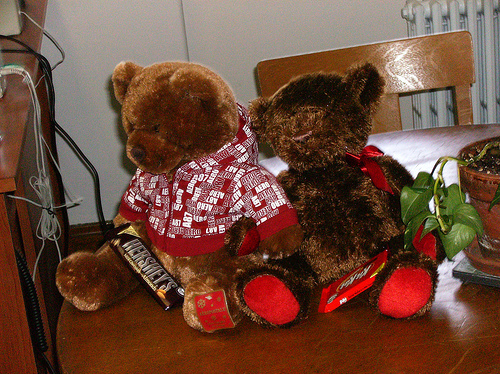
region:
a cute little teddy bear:
[51, 59, 303, 334]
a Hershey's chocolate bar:
[107, 226, 188, 317]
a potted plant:
[398, 133, 497, 288]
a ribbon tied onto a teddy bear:
[341, 141, 396, 200]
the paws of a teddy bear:
[230, 256, 442, 328]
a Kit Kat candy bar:
[314, 248, 394, 317]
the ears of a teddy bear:
[110, 56, 225, 109]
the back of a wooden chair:
[254, 26, 480, 129]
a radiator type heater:
[391, 1, 498, 131]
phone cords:
[2, 57, 85, 288]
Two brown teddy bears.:
[42, 21, 482, 335]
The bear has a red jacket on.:
[49, 67, 278, 339]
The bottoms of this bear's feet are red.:
[240, 262, 450, 335]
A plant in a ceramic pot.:
[400, 108, 497, 287]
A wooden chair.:
[250, 27, 479, 144]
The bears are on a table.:
[39, 9, 489, 372]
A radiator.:
[392, 1, 496, 121]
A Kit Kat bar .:
[302, 226, 410, 335]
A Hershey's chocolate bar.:
[103, 221, 195, 324]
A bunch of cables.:
[15, 22, 100, 273]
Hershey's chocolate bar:
[95, 215, 188, 315]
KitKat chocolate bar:
[310, 245, 392, 315]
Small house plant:
[395, 130, 499, 284]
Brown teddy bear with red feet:
[222, 50, 442, 335]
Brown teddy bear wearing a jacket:
[45, 55, 305, 335]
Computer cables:
[0, 0, 110, 287]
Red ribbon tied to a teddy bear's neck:
[235, 55, 407, 195]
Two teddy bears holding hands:
[42, 55, 444, 336]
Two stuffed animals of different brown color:
[50, 56, 445, 336]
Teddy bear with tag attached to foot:
[50, 56, 309, 338]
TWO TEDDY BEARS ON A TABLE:
[49, 49, 444, 339]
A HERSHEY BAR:
[107, 212, 194, 313]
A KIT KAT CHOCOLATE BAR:
[315, 243, 403, 319]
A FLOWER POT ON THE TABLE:
[394, 116, 499, 289]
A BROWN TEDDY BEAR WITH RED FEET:
[229, 56, 439, 329]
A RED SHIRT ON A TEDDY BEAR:
[49, 51, 308, 334]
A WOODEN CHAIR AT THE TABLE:
[252, 21, 491, 141]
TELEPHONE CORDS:
[0, 58, 87, 286]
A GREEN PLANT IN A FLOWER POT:
[395, 130, 497, 288]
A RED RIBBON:
[342, 138, 404, 204]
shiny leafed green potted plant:
[394, 134, 497, 271]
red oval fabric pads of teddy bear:
[378, 257, 428, 314]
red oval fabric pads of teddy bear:
[238, 272, 298, 322]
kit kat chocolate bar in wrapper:
[318, 250, 388, 309]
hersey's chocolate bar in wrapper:
[108, 219, 185, 307]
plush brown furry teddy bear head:
[106, 60, 234, 168]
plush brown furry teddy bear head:
[249, 58, 382, 168]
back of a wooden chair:
[253, 34, 477, 138]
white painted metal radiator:
[397, 2, 499, 136]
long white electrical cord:
[1, 68, 56, 287]